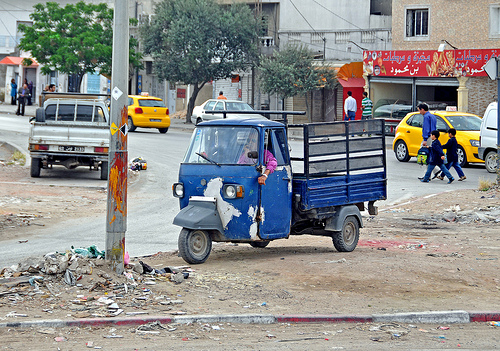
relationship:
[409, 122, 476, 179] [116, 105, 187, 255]
kids on street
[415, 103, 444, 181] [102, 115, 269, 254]
man on street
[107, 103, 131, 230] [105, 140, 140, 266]
paint on pole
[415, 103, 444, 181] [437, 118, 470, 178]
man with two boy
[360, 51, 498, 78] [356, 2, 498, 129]
sign on building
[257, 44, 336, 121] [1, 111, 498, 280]
trees beside street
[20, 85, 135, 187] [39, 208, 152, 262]
pickup truck on street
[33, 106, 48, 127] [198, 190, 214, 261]
tire in pickup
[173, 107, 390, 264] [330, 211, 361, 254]
vehicle with wheel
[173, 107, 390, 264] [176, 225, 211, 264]
vehicle with wheel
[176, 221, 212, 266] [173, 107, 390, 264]
front wheel of vehicle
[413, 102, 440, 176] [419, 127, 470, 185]
man holding kids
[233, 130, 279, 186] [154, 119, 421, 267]
person inside vehicle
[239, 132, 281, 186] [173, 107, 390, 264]
person inside vehicle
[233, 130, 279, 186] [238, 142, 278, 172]
person wears clothes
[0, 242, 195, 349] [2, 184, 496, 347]
debris on ground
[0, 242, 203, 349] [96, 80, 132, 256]
debris under pole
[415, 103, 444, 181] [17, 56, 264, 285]
man crossing street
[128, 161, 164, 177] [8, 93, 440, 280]
garbage in street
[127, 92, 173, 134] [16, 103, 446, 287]
cab in street